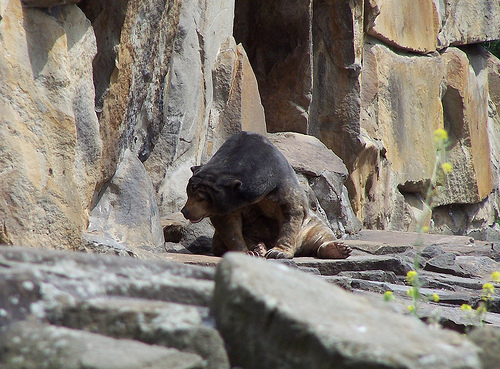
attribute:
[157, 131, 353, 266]
bear — sitting, black, brown, panting, large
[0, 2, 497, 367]
rock — grey, flat, out of focus, cracked, gray, huge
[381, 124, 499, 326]
flower — yellow, green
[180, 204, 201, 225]
nose — black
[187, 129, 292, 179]
hair — short